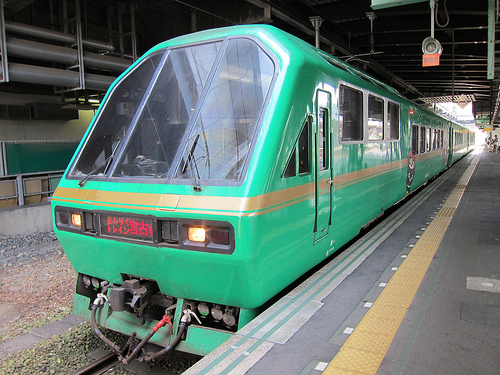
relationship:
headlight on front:
[69, 213, 81, 226] [50, 20, 303, 357]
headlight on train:
[69, 213, 81, 226] [49, 18, 476, 353]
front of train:
[50, 20, 303, 357] [49, 18, 476, 353]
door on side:
[311, 85, 336, 246] [258, 69, 410, 304]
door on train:
[311, 85, 336, 246] [49, 18, 476, 353]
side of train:
[258, 69, 410, 304] [49, 18, 476, 353]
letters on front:
[108, 215, 154, 239] [50, 20, 304, 364]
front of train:
[50, 20, 304, 364] [49, 18, 476, 353]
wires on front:
[90, 289, 201, 359] [50, 20, 303, 357]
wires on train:
[90, 289, 201, 359] [49, 18, 476, 353]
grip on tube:
[152, 311, 175, 330] [122, 327, 155, 361]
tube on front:
[122, 327, 155, 361] [50, 20, 303, 357]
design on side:
[402, 145, 417, 200] [376, 100, 446, 195]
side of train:
[376, 100, 446, 195] [49, 18, 476, 353]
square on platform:
[315, 359, 329, 372] [279, 225, 483, 373]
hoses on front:
[123, 303, 201, 371] [50, 20, 303, 357]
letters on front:
[106, 215, 154, 239] [50, 20, 303, 357]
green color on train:
[250, 225, 308, 269] [49, 18, 476, 353]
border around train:
[49, 157, 399, 219] [49, 18, 476, 353]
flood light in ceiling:
[417, 38, 441, 55] [394, 11, 484, 79]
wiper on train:
[179, 135, 199, 191] [49, 18, 476, 353]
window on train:
[364, 88, 388, 139] [49, 18, 476, 353]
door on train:
[310, 85, 338, 239] [49, 18, 476, 353]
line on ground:
[325, 295, 413, 373] [184, 222, 485, 372]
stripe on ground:
[285, 304, 303, 337] [184, 242, 484, 372]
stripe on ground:
[260, 293, 293, 315] [184, 242, 484, 372]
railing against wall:
[4, 163, 63, 204] [6, 5, 378, 210]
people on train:
[480, 131, 497, 158] [49, 18, 476, 353]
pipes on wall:
[2, 23, 136, 98] [6, 5, 378, 210]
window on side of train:
[332, 82, 373, 142] [49, 18, 476, 353]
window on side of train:
[364, 88, 388, 139] [49, 18, 476, 353]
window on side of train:
[384, 98, 403, 144] [49, 18, 476, 353]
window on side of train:
[410, 122, 420, 163] [49, 18, 476, 353]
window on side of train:
[418, 119, 430, 151] [49, 18, 476, 353]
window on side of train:
[423, 124, 436, 157] [49, 18, 476, 353]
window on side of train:
[434, 126, 441, 148] [49, 18, 476, 353]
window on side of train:
[440, 126, 450, 149] [49, 18, 476, 353]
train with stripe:
[49, 18, 476, 353] [60, 138, 477, 221]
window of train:
[63, 41, 264, 191] [49, 18, 476, 353]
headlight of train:
[59, 203, 205, 258] [28, 23, 483, 363]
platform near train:
[184, 138, 499, 371] [49, 18, 476, 353]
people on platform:
[486, 131, 497, 152] [184, 138, 499, 371]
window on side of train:
[332, 82, 366, 142] [49, 18, 476, 353]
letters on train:
[106, 215, 154, 239] [49, 18, 476, 353]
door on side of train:
[311, 85, 336, 246] [49, 18, 476, 353]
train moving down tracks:
[49, 18, 476, 353] [15, 334, 175, 373]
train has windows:
[49, 18, 476, 353] [76, 35, 282, 195]